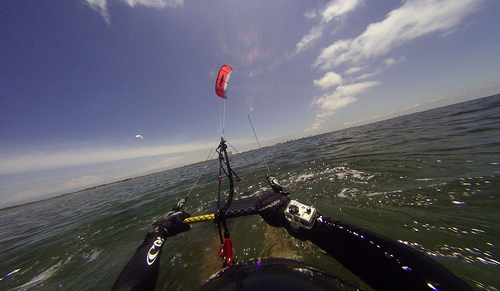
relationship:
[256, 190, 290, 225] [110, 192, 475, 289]
glove of person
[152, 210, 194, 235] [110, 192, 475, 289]
glove of person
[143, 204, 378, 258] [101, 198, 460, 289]
arms of wetsuit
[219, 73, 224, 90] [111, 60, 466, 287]
spot on parachute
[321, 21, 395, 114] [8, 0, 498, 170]
clouds wearing sky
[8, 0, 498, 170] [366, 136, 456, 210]
sky above ocean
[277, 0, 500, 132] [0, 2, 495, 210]
clouds in sky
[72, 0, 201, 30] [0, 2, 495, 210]
clouds in sky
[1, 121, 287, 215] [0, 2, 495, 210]
clouds in sky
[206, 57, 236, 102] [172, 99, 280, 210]
kite attached to ropes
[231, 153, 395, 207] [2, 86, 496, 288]
foam in water water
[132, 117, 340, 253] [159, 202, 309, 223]
harness with writing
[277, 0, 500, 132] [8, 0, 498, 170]
clouds with sky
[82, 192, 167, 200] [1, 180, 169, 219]
land in background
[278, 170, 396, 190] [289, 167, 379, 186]
tops of wave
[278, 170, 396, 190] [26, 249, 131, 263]
tops of wave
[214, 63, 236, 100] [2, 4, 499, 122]
kite in air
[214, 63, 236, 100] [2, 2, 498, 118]
kite in sky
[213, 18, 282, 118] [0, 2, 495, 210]
light in sky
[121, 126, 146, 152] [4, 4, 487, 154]
kite in sky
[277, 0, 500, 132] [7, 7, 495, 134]
clouds in sky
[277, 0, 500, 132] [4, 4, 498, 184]
clouds in sky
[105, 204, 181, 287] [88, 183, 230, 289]
arm of person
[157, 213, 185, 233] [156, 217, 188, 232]
hand wearing glove